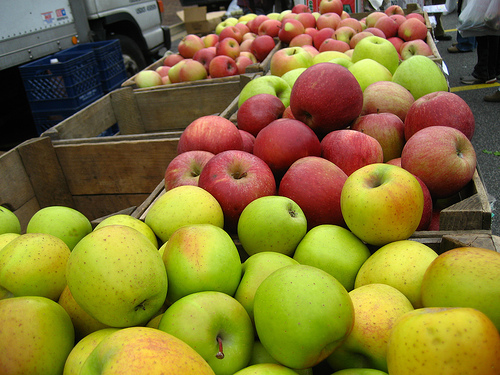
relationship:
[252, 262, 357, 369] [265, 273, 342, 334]
green apple has spots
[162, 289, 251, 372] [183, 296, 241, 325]
apple has spots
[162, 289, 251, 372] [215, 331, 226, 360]
apple has stem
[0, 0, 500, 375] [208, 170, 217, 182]
apple has spot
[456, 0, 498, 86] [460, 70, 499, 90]
person has shoe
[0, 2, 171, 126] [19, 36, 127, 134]
side next to crates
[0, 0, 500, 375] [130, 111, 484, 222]
apple in tray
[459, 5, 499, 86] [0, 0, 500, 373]
person standing near fruit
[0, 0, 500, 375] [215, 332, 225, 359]
apple has stem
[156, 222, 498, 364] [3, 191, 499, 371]
crates has apples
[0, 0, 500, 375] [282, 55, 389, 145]
apple has apple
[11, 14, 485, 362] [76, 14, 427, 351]
cases have apples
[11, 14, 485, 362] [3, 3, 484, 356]
cases are at market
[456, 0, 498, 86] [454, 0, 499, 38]
person holding bag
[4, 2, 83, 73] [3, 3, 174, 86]
side of truck